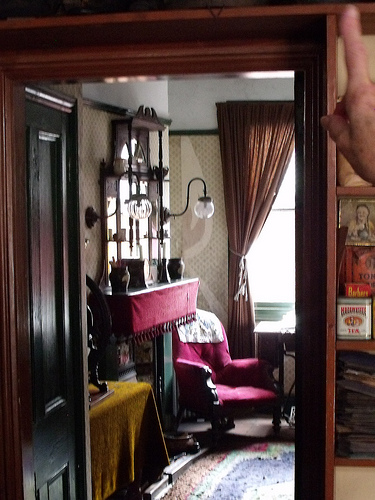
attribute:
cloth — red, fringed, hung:
[111, 294, 197, 327]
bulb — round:
[194, 201, 214, 219]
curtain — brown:
[213, 99, 291, 356]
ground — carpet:
[157, 408, 372, 497]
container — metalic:
[338, 302, 370, 340]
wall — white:
[176, 86, 218, 126]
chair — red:
[132, 296, 308, 424]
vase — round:
[165, 255, 188, 279]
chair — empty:
[173, 309, 279, 431]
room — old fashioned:
[0, 1, 371, 499]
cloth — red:
[102, 278, 199, 344]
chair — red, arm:
[155, 301, 298, 445]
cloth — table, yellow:
[88, 373, 178, 499]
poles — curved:
[104, 155, 217, 259]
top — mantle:
[92, 264, 203, 296]